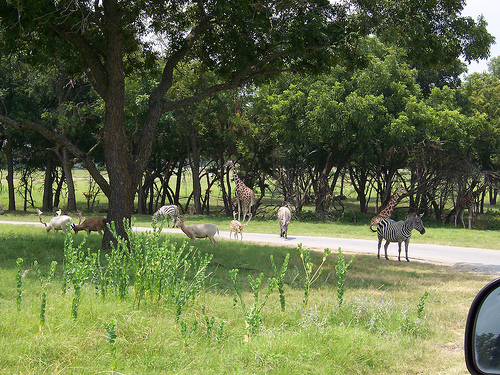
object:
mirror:
[473, 285, 499, 374]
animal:
[274, 204, 292, 240]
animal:
[372, 212, 426, 263]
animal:
[173, 204, 220, 248]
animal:
[150, 204, 184, 229]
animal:
[67, 212, 112, 237]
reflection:
[473, 331, 499, 370]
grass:
[0, 167, 498, 374]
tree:
[152, 58, 234, 214]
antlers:
[34, 207, 50, 227]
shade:
[0, 230, 499, 298]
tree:
[473, 74, 499, 204]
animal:
[450, 181, 493, 229]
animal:
[367, 185, 408, 227]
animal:
[227, 211, 252, 241]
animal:
[203, 187, 211, 194]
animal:
[221, 159, 257, 222]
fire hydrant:
[304, 50, 416, 195]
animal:
[35, 208, 73, 236]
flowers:
[296, 303, 328, 328]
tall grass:
[12, 255, 27, 317]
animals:
[367, 210, 425, 263]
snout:
[419, 228, 424, 234]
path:
[0, 221, 499, 277]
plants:
[334, 246, 356, 307]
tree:
[0, 0, 334, 250]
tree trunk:
[100, 0, 136, 253]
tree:
[417, 107, 486, 227]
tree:
[334, 96, 388, 214]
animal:
[81, 191, 97, 201]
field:
[0, 167, 499, 374]